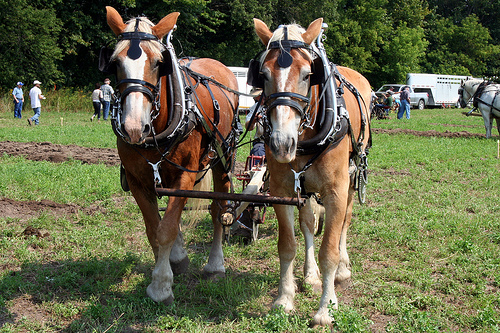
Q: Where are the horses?
A: In a field.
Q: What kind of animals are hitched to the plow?
A: Horses.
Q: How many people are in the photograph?
A: Seven.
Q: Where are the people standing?
A: Behind the horses.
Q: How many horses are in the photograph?
A: Three.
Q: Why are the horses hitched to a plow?
A: To plow the field.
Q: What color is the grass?
A: Green.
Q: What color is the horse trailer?
A: White.